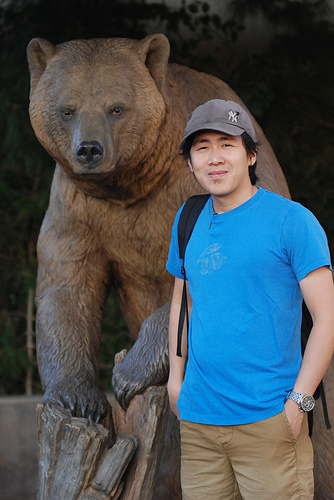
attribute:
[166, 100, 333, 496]
man — smiling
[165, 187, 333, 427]
shirt — blue, bright blue, short sleeved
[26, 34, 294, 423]
bear — wooden, brown, statue, grizzly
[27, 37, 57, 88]
left ear — brown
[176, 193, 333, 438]
backpack — black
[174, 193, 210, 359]
strap — black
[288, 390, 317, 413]
watch — silver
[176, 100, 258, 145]
hat — gray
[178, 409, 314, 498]
pants — beige, tan, khaki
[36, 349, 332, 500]
log base — statue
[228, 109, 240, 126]
logo — white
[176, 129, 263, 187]
hair — black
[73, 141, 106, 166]
nose — black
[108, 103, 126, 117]
right eye — brown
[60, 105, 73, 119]
left eye — brown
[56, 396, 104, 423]
claws — long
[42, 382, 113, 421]
paw — large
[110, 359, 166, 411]
paw — large